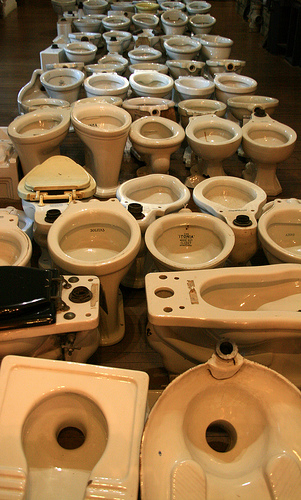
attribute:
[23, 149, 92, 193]
toilet seat — triangle, closed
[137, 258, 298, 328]
toilet — on the ground, long, missing lid, on ground, white, right angle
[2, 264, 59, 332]
toilet seat — black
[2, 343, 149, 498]
toilet — square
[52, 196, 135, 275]
fixture — round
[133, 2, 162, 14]
toilet — yellow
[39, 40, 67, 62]
tank — rectangular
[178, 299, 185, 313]
hole — small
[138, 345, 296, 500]
sink — new, big, glass, many, white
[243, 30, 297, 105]
floor — wood, brown, wooden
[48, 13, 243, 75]
toilets — thin, large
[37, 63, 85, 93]
toilet — white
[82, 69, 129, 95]
toilet — white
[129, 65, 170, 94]
toilet — white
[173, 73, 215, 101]
toilet — white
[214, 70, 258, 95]
toilet — white